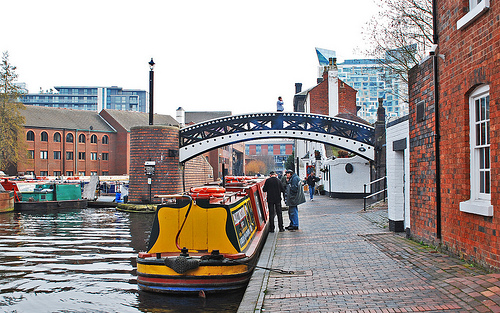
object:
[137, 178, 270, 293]
boats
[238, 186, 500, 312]
walkway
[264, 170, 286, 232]
person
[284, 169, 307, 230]
person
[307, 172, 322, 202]
person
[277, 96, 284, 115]
person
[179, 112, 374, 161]
overpass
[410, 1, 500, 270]
building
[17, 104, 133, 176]
building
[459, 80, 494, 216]
window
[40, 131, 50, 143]
window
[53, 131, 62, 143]
window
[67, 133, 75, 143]
window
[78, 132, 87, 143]
window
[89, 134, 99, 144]
window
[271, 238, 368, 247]
lines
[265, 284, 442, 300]
lines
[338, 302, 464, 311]
lines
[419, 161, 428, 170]
bricks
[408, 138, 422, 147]
bricks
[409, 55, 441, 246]
wall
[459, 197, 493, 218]
windowsill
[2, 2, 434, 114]
sky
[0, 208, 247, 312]
water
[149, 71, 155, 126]
post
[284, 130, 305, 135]
spots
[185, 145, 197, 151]
spots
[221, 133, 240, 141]
spots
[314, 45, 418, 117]
building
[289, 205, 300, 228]
jeans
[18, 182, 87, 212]
boat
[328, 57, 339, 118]
chimney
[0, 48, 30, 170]
tree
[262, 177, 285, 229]
clothes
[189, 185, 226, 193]
lifesaver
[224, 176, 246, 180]
lifesaver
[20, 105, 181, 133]
roof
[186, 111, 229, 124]
roof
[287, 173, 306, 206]
jacket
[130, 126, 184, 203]
pillar